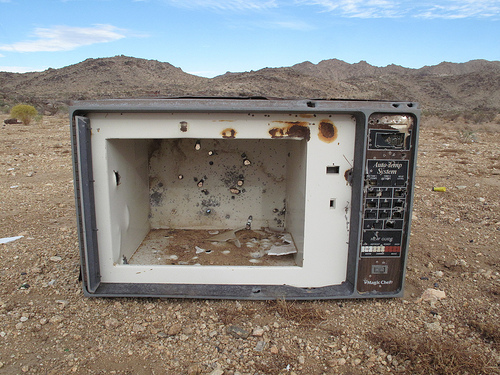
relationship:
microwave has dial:
[69, 92, 425, 305] [365, 125, 414, 154]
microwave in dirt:
[69, 92, 425, 305] [0, 114, 500, 374]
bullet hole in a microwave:
[192, 175, 209, 192] [69, 92, 425, 305]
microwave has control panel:
[69, 92, 425, 305] [352, 105, 419, 293]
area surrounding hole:
[316, 115, 344, 147] [323, 124, 334, 136]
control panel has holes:
[352, 105, 419, 293] [367, 186, 408, 231]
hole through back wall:
[204, 155, 216, 172] [147, 137, 292, 234]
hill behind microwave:
[1, 54, 499, 128] [69, 92, 425, 305]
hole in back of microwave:
[204, 155, 216, 172] [69, 92, 425, 305]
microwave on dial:
[69, 92, 425, 305] [365, 125, 414, 154]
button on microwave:
[379, 193, 394, 210] [69, 92, 425, 305]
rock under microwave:
[102, 309, 124, 335] [69, 92, 425, 305]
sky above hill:
[1, 2, 499, 76] [1, 54, 499, 128]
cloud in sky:
[1, 20, 121, 56] [1, 2, 499, 76]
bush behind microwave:
[6, 97, 44, 121] [69, 92, 425, 305]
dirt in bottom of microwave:
[148, 227, 301, 267] [69, 92, 425, 305]